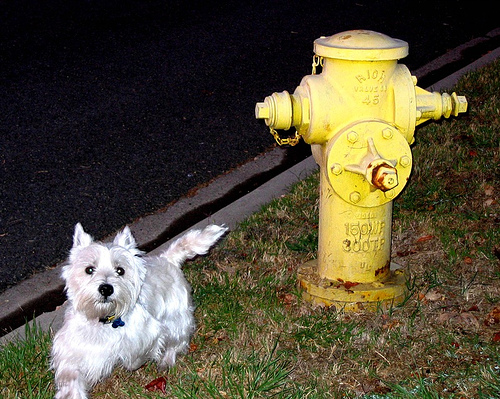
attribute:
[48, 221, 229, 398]
dog — small, white, cute, looking at camera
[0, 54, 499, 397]
grass — green, dry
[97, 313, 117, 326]
collar — blue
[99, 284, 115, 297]
nose — small, black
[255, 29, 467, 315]
fire hydrant — yellow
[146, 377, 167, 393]
leaf — dry, small, red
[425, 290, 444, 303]
leaf — dry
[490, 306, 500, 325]
leaf — dry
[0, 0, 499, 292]
road — made of asphalt, with tarmac, dark grey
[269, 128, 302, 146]
chain — covered with paint, yellow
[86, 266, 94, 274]
eye — black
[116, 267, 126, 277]
eye — black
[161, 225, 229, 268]
tail — white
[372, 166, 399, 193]
nut — rust covered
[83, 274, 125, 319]
muzzle — black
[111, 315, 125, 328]
name tag — blue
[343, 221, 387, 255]
lettering — raised